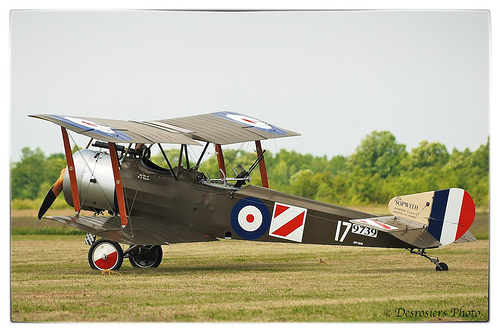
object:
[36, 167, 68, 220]
propellar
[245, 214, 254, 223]
dot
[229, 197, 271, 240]
circle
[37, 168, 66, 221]
perpeller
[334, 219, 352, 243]
number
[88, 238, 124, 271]
wheel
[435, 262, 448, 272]
wheel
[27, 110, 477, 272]
airplane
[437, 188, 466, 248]
stripes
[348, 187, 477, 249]
tail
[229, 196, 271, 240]
target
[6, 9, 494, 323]
area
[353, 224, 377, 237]
id number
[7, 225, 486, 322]
grass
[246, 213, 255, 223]
player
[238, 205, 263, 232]
ring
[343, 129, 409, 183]
nice trees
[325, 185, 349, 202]
foliage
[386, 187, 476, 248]
stripes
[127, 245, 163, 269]
wheel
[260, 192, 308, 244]
box